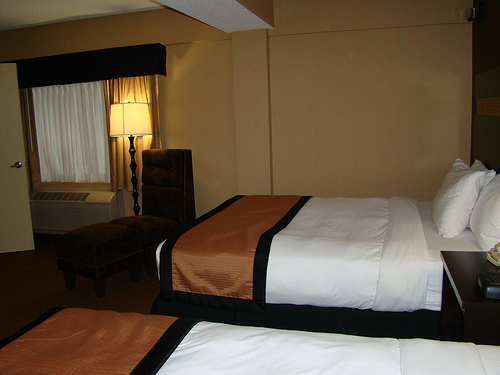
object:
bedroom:
[0, 0, 500, 375]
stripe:
[159, 194, 313, 315]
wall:
[273, 29, 462, 130]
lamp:
[108, 101, 154, 217]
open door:
[0, 63, 36, 254]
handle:
[14, 161, 22, 169]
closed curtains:
[30, 75, 162, 192]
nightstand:
[438, 250, 499, 345]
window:
[19, 74, 161, 191]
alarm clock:
[476, 270, 500, 300]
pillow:
[431, 158, 487, 239]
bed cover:
[159, 194, 430, 316]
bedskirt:
[155, 249, 445, 318]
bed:
[155, 158, 500, 325]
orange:
[171, 194, 304, 300]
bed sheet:
[416, 201, 480, 312]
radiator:
[28, 189, 125, 235]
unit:
[30, 188, 127, 236]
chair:
[55, 213, 183, 299]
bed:
[0, 307, 500, 375]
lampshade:
[109, 101, 154, 138]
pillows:
[431, 158, 500, 252]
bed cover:
[1, 306, 488, 375]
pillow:
[468, 173, 500, 252]